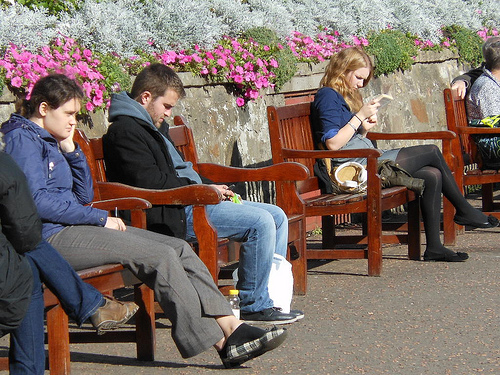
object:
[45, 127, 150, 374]
chair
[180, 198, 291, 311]
jeans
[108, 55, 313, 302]
man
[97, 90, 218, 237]
jacket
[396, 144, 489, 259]
tights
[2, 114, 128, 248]
blue jacket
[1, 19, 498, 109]
flowers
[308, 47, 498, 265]
lady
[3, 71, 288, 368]
lady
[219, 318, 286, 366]
shoes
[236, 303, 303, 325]
shoes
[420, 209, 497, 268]
shoes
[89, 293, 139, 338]
shoes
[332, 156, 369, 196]
headphones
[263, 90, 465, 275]
bench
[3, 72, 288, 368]
woman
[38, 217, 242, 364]
pants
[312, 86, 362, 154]
jacket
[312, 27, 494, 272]
woman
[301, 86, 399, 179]
dress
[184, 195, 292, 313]
blue jeans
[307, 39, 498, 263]
girl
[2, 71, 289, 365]
girl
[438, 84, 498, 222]
bench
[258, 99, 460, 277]
bench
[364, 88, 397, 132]
book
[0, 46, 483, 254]
wall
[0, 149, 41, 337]
jacket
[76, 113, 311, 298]
bench